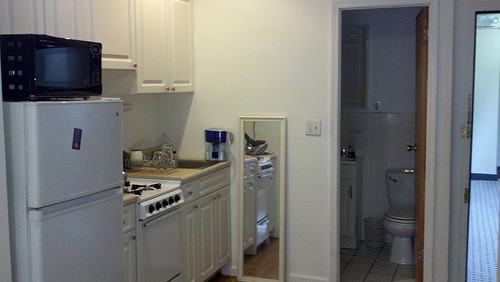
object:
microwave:
[1, 33, 103, 100]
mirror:
[463, 8, 498, 282]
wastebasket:
[363, 217, 385, 250]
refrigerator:
[1, 96, 126, 282]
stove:
[120, 177, 183, 221]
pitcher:
[202, 128, 234, 162]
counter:
[123, 151, 230, 179]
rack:
[122, 147, 177, 176]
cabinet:
[341, 158, 365, 252]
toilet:
[382, 207, 413, 267]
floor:
[340, 241, 419, 281]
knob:
[349, 184, 354, 200]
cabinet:
[131, 0, 195, 96]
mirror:
[340, 24, 371, 112]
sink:
[348, 151, 356, 158]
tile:
[345, 255, 378, 264]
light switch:
[305, 120, 321, 136]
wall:
[146, 1, 341, 282]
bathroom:
[337, 2, 431, 281]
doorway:
[326, 3, 439, 281]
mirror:
[235, 115, 288, 282]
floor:
[209, 271, 237, 281]